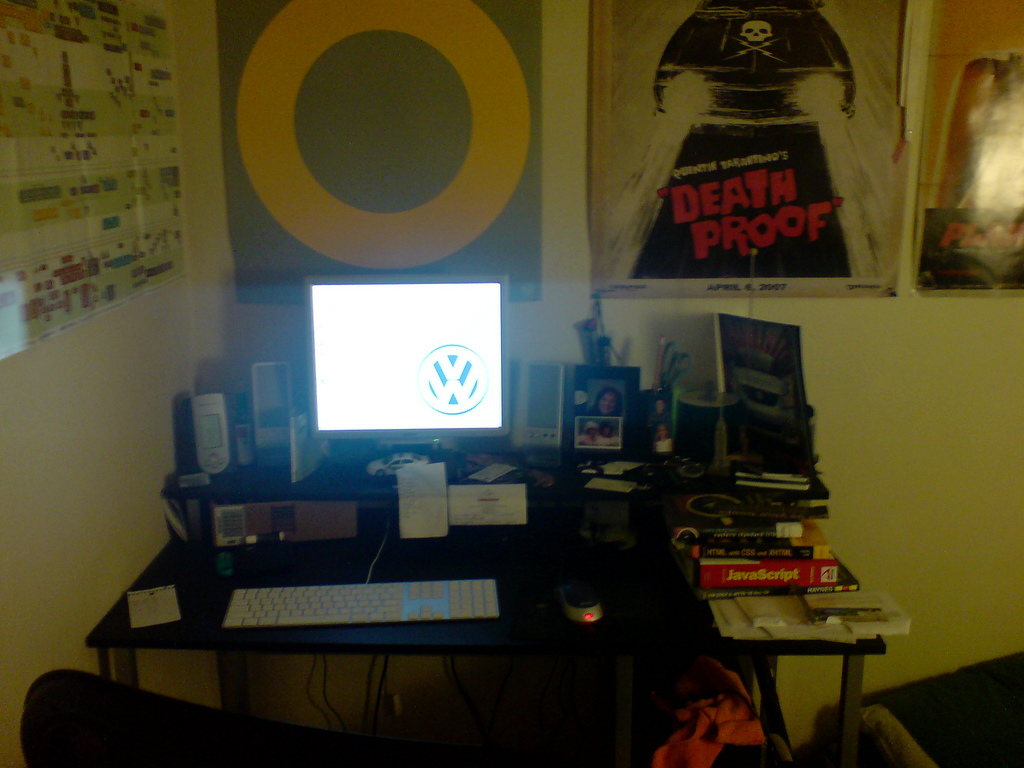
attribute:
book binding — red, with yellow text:
[695, 552, 838, 591]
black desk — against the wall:
[88, 383, 894, 740]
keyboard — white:
[210, 560, 507, 632]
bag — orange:
[644, 648, 776, 765]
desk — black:
[76, 459, 943, 764]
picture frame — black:
[559, 351, 644, 468]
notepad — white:
[115, 569, 191, 636]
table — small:
[73, 435, 905, 764]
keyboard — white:
[214, 565, 506, 637]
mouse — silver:
[549, 573, 608, 626]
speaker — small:
[183, 381, 238, 485]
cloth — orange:
[626, 657, 776, 764]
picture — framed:
[539, 346, 671, 481]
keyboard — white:
[222, 549, 609, 670]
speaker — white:
[166, 357, 287, 474]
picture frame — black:
[533, 359, 678, 493]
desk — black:
[120, 482, 829, 711]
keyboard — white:
[216, 547, 558, 627]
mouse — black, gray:
[526, 549, 665, 653]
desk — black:
[127, 482, 871, 761]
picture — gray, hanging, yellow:
[216, 7, 593, 319]